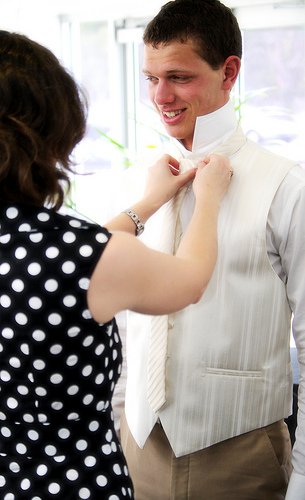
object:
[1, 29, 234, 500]
woman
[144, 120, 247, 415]
tie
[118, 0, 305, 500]
man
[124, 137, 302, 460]
vest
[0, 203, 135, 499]
dress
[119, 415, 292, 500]
pant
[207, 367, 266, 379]
pocket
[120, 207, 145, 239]
watch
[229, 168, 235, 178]
ring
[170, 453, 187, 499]
zipper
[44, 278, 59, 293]
dot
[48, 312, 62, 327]
dot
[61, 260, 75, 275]
dot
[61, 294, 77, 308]
dot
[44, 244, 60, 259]
dot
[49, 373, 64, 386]
dot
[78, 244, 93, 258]
dot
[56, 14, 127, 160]
window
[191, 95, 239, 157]
collar